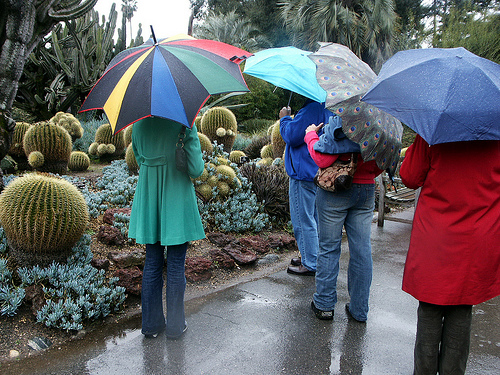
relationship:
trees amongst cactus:
[187, 2, 402, 74] [201, 105, 237, 155]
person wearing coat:
[132, 120, 204, 339] [125, 115, 211, 253]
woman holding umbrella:
[303, 112, 386, 322] [309, 40, 403, 177]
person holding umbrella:
[399, 134, 500, 375] [363, 39, 498, 151]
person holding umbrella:
[132, 120, 204, 339] [79, 23, 258, 132]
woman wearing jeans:
[303, 112, 386, 322] [309, 182, 374, 322]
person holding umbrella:
[132, 120, 204, 339] [73, 24, 252, 136]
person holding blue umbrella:
[399, 134, 500, 375] [375, 44, 492, 136]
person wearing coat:
[132, 120, 204, 339] [127, 117, 207, 245]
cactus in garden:
[0, 107, 294, 255] [2, 0, 294, 362]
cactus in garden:
[200, 104, 237, 144] [2, 0, 294, 362]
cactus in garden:
[94, 122, 124, 156] [2, 0, 294, 362]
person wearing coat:
[399, 134, 497, 371] [397, 132, 498, 304]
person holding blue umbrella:
[399, 134, 497, 371] [360, 47, 500, 146]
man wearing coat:
[278, 99, 335, 276] [277, 99, 329, 188]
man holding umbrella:
[278, 99, 335, 276] [244, 37, 328, 108]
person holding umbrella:
[131, 120, 205, 342] [79, 39, 254, 133]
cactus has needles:
[0, 107, 294, 255] [7, 166, 87, 253]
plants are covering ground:
[8, 260, 128, 336] [0, 160, 295, 365]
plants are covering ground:
[0, 107, 294, 332] [0, 160, 295, 365]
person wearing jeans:
[132, 120, 204, 339] [136, 242, 185, 341]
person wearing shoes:
[132, 120, 204, 339] [143, 324, 191, 343]